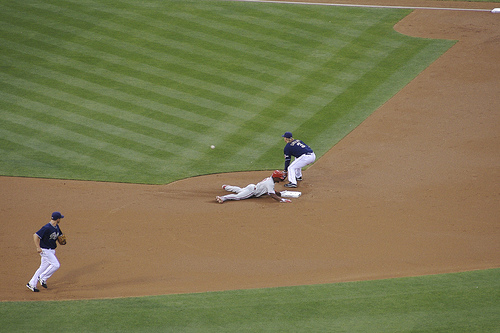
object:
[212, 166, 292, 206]
player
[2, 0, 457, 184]
grass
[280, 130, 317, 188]
baseman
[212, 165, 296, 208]
baseball player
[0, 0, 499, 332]
ground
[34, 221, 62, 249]
shirt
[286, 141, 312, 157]
shirt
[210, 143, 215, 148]
ball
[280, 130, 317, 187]
player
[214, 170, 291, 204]
man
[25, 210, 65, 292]
player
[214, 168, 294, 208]
runner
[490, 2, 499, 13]
base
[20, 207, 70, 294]
man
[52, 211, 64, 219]
hat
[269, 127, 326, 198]
man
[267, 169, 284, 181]
helmet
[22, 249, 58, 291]
pants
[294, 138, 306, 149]
number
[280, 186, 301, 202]
base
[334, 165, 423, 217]
sand